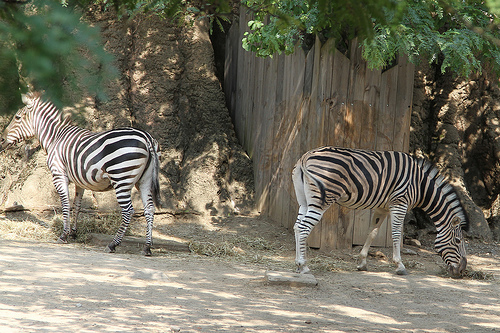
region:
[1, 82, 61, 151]
the head of a zebra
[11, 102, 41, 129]
the eye of a zebra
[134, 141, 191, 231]
the tail of a zebra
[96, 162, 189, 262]
the legs of a zebra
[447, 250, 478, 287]
the mouth of a zebra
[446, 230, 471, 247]
the eye of a zebra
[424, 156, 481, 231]
the main of a zebra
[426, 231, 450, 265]
the jaw of a zebra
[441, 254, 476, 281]
the nose of a zebra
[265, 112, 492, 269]
the body of a zebra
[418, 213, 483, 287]
head of a zebra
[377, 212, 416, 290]
leg of a zebra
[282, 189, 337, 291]
leg of a zebra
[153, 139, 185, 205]
tail of a zebra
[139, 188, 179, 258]
leg of a zebra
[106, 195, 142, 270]
leg of a zebra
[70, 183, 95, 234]
leg of a zebra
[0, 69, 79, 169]
head of a zebra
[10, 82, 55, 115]
ear of a zebra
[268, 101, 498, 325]
this is a zebra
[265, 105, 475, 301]
black stripes on zebra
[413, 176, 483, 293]
zebra has head down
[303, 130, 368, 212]
brown stripes on zebra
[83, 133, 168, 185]
white background on zebra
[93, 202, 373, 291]
yellow hay on ground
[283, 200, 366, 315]
bag legs of zebra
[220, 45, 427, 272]
brown fence next to zebra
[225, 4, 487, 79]
a green tree limb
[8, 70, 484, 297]
zebras facing opposite directions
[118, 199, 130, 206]
blacks stripe on zebra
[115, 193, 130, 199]
blacks stripe on zebra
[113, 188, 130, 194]
blacks stripe on zebra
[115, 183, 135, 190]
blacks stripe on zebra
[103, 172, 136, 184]
blacks stripe on zebra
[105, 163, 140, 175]
blacks stripe on zebra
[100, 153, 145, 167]
blacks stripe on zebra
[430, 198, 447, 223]
blacks stripe on zebra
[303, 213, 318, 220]
blacks stripe on zebra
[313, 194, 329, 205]
blacks stripe on zebra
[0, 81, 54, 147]
the head of a zebra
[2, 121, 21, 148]
the mouth of a zebra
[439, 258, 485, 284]
the nose of a zebra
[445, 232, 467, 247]
the eye of a zebra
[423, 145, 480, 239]
the main of a zebra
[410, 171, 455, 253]
the neck of a zebra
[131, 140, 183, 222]
the tail of a zebra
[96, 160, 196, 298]
the legs of a zebra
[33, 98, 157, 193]
the body of a zebra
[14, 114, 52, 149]
the jaw of a zebra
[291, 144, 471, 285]
zebra is smelling the ground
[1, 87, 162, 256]
zebra is beside the tree trunk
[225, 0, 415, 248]
board is made of wood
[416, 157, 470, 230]
hair is on zebras neck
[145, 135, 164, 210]
tail is behind zebra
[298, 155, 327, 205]
tail is swinging